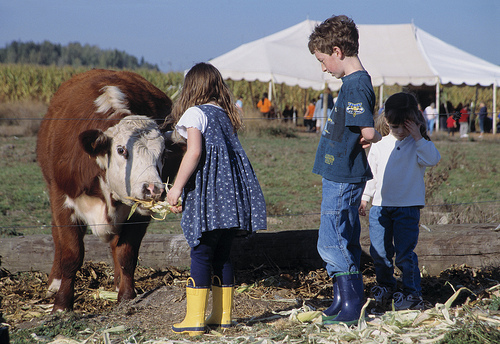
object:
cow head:
[78, 113, 173, 215]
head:
[77, 114, 181, 218]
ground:
[3, 123, 499, 344]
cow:
[32, 66, 174, 307]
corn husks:
[122, 177, 180, 221]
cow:
[36, 68, 173, 316]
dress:
[174, 101, 268, 248]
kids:
[159, 8, 446, 343]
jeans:
[363, 203, 425, 300]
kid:
[355, 88, 441, 318]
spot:
[92, 85, 132, 116]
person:
[256, 90, 273, 118]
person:
[302, 99, 316, 131]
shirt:
[256, 95, 272, 112]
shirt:
[303, 103, 318, 119]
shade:
[256, 227, 329, 292]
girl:
[160, 62, 272, 340]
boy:
[307, 11, 384, 318]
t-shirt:
[309, 68, 378, 183]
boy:
[304, 10, 379, 325]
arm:
[341, 80, 386, 140]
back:
[353, 73, 376, 178]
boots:
[305, 265, 372, 330]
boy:
[359, 91, 440, 321]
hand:
[402, 118, 423, 140]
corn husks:
[291, 281, 493, 343]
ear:
[76, 128, 110, 158]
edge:
[186, 220, 268, 248]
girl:
[152, 60, 283, 335]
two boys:
[289, 17, 452, 304]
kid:
[165, 57, 268, 338]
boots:
[167, 272, 239, 337]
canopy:
[169, 22, 499, 135]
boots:
[314, 270, 370, 326]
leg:
[51, 190, 83, 310]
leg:
[116, 224, 145, 302]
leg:
[41, 180, 73, 300]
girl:
[144, 59, 273, 337]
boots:
[173, 277, 233, 336]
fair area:
[176, 17, 496, 146]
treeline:
[3, 34, 164, 79]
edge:
[332, 270, 364, 279]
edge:
[170, 325, 209, 335]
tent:
[178, 15, 499, 125]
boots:
[170, 284, 235, 338]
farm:
[21, 10, 488, 341]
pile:
[282, 286, 493, 344]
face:
[105, 114, 173, 208]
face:
[386, 109, 423, 141]